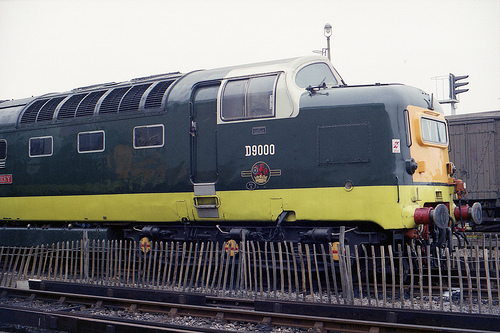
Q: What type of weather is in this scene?
A: It is cloudy.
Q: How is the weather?
A: It is cloudy.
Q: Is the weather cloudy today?
A: Yes, it is cloudy.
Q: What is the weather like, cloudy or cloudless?
A: It is cloudy.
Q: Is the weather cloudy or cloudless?
A: It is cloudy.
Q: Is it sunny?
A: No, it is cloudy.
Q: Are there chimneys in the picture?
A: No, there are no chimneys.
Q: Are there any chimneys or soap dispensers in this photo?
A: No, there are no chimneys or soap dispensers.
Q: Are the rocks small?
A: Yes, the rocks are small.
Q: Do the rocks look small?
A: Yes, the rocks are small.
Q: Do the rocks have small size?
A: Yes, the rocks are small.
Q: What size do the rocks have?
A: The rocks have small size.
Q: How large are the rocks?
A: The rocks are small.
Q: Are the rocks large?
A: No, the rocks are small.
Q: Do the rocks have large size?
A: No, the rocks are small.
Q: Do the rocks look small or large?
A: The rocks are small.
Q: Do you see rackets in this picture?
A: No, there are no rackets.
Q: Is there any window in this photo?
A: Yes, there are windows.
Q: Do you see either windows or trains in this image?
A: Yes, there are windows.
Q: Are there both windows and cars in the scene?
A: Yes, there are both windows and a car.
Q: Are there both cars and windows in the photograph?
A: Yes, there are both windows and a car.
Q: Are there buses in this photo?
A: No, there are no buses.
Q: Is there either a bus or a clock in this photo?
A: No, there are no buses or clocks.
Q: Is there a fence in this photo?
A: Yes, there is a fence.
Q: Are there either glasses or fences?
A: Yes, there is a fence.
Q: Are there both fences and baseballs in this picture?
A: No, there is a fence but no baseballs.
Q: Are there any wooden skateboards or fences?
A: Yes, there is a wood fence.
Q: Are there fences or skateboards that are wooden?
A: Yes, the fence is wooden.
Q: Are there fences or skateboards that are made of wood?
A: Yes, the fence is made of wood.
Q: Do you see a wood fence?
A: Yes, there is a fence that is made of wood.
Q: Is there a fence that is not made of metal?
A: Yes, there is a fence that is made of wood.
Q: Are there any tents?
A: No, there are no tents.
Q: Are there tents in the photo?
A: No, there are no tents.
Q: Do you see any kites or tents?
A: No, there are no tents or kites.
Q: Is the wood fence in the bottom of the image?
A: Yes, the fence is in the bottom of the image.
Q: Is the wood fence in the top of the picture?
A: No, the fence is in the bottom of the image.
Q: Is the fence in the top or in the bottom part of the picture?
A: The fence is in the bottom of the image.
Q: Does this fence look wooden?
A: Yes, the fence is wooden.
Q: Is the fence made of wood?
A: Yes, the fence is made of wood.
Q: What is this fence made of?
A: The fence is made of wood.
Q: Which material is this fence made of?
A: The fence is made of wood.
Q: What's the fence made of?
A: The fence is made of wood.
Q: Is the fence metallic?
A: No, the fence is wooden.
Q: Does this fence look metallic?
A: No, the fence is wooden.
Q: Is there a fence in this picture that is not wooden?
A: No, there is a fence but it is wooden.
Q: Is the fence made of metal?
A: No, the fence is made of wood.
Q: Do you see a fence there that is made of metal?
A: No, there is a fence but it is made of wood.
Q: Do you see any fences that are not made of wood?
A: No, there is a fence but it is made of wood.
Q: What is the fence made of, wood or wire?
A: The fence is made of wood.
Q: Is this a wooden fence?
A: Yes, this is a wooden fence.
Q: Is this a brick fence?
A: No, this is a wooden fence.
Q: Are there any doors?
A: Yes, there is a door.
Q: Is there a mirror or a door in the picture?
A: Yes, there is a door.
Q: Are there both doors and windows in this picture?
A: Yes, there are both a door and windows.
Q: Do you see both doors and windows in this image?
A: Yes, there are both a door and windows.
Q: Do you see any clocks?
A: No, there are no clocks.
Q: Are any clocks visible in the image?
A: No, there are no clocks.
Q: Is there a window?
A: Yes, there is a window.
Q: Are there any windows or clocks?
A: Yes, there is a window.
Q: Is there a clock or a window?
A: Yes, there is a window.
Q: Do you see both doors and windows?
A: Yes, there are both a window and doors.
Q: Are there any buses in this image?
A: No, there are no buses.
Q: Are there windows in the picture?
A: Yes, there is a window.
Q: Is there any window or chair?
A: Yes, there is a window.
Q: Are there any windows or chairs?
A: Yes, there is a window.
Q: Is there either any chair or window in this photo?
A: Yes, there is a window.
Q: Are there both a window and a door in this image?
A: Yes, there are both a window and a door.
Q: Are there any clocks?
A: No, there are no clocks.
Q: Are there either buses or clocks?
A: No, there are no clocks or buses.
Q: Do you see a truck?
A: No, there are no trucks.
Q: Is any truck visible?
A: No, there are no trucks.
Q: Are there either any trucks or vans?
A: No, there are no trucks or vans.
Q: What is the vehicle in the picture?
A: The vehicle is a car.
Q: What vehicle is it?
A: The vehicle is a car.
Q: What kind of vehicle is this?
A: This is a car.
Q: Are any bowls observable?
A: No, there are no bowls.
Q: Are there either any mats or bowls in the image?
A: No, there are no bowls or mats.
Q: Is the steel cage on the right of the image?
A: Yes, the cage is on the right of the image.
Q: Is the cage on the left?
A: No, the cage is on the right of the image.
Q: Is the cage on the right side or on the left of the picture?
A: The cage is on the right of the image.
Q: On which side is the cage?
A: The cage is on the right of the image.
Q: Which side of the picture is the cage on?
A: The cage is on the right of the image.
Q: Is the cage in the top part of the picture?
A: Yes, the cage is in the top of the image.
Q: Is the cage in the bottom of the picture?
A: No, the cage is in the top of the image.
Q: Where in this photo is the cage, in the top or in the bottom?
A: The cage is in the top of the image.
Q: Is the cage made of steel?
A: Yes, the cage is made of steel.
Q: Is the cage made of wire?
A: No, the cage is made of steel.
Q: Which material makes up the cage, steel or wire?
A: The cage is made of steel.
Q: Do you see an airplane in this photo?
A: No, there are no airplanes.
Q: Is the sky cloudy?
A: Yes, the sky is cloudy.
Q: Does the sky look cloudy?
A: Yes, the sky is cloudy.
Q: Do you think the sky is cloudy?
A: Yes, the sky is cloudy.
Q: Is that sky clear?
A: No, the sky is cloudy.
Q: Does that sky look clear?
A: No, the sky is cloudy.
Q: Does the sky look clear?
A: No, the sky is cloudy.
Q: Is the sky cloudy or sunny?
A: The sky is cloudy.